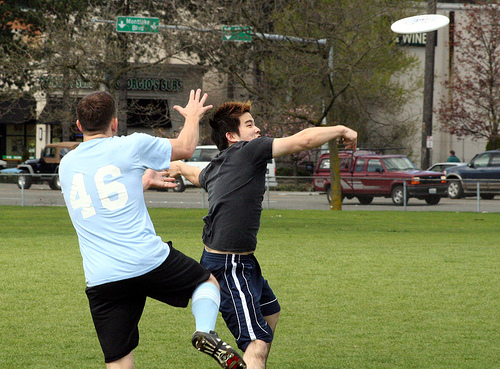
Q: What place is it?
A: It is a field.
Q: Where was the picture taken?
A: It was taken at the field.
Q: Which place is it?
A: It is a field.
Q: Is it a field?
A: Yes, it is a field.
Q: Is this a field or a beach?
A: It is a field.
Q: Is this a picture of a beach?
A: No, the picture is showing a field.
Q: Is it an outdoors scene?
A: Yes, it is outdoors.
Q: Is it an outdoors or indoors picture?
A: It is outdoors.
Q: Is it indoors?
A: No, it is outdoors.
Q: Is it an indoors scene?
A: No, it is outdoors.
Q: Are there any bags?
A: No, there are no bags.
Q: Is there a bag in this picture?
A: No, there are no bags.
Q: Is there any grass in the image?
A: Yes, there is grass.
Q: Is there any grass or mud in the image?
A: Yes, there is grass.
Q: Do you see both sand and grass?
A: No, there is grass but no sand.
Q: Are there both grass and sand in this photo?
A: No, there is grass but no sand.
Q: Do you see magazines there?
A: No, there are no magazines.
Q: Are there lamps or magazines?
A: No, there are no magazines or lamps.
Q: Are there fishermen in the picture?
A: No, there are no fishermen.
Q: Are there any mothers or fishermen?
A: No, there are no fishermen or mothers.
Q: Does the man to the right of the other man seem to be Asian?
A: Yes, the man is asian.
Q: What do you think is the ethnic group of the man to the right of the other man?
A: The man is asian.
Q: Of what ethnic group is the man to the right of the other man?
A: The man is asian.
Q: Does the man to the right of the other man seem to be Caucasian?
A: No, the man is asian.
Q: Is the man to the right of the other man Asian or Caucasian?
A: The man is asian.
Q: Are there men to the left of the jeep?
A: No, the man is to the right of the jeep.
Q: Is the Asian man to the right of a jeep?
A: Yes, the man is to the right of a jeep.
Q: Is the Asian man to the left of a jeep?
A: No, the man is to the right of a jeep.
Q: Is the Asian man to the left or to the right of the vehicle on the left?
A: The man is to the right of the jeep.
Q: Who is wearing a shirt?
A: The man is wearing a shirt.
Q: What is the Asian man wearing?
A: The man is wearing a shirt.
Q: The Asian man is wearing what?
A: The man is wearing a shirt.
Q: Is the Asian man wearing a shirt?
A: Yes, the man is wearing a shirt.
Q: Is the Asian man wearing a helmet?
A: No, the man is wearing a shirt.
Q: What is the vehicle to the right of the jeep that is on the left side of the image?
A: The vehicle is a van.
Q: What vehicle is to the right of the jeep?
A: The vehicle is a van.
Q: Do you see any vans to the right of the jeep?
A: Yes, there is a van to the right of the jeep.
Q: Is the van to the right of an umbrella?
A: No, the van is to the right of the jeep.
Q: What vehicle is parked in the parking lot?
A: The vehicle is a van.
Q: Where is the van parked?
A: The van is parked in the parking lot.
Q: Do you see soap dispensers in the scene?
A: No, there are no soap dispensers.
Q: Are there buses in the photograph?
A: No, there are no buses.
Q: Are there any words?
A: Yes, there are words.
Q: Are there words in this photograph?
A: Yes, there are words.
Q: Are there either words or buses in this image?
A: Yes, there are words.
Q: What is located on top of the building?
A: The words are on top of the building.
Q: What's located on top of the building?
A: The words are on top of the building.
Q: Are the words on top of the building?
A: Yes, the words are on top of the building.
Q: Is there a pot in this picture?
A: No, there are no pots.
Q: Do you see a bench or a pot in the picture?
A: No, there are no pots or benches.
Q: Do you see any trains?
A: No, there are no trains.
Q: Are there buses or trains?
A: No, there are no trains or buses.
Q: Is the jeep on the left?
A: Yes, the jeep is on the left of the image.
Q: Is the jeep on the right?
A: No, the jeep is on the left of the image.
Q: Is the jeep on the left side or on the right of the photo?
A: The jeep is on the left of the image.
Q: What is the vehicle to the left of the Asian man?
A: The vehicle is a jeep.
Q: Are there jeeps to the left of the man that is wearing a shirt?
A: Yes, there is a jeep to the left of the man.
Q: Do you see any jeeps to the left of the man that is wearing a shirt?
A: Yes, there is a jeep to the left of the man.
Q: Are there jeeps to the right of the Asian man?
A: No, the jeep is to the left of the man.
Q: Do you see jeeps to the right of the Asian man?
A: No, the jeep is to the left of the man.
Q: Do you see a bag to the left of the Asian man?
A: No, there is a jeep to the left of the man.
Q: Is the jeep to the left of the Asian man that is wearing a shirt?
A: Yes, the jeep is to the left of the man.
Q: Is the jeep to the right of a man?
A: No, the jeep is to the left of a man.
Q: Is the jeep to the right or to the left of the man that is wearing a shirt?
A: The jeep is to the left of the man.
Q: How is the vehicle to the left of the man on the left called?
A: The vehicle is a jeep.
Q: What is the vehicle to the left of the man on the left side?
A: The vehicle is a jeep.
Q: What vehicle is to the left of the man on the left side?
A: The vehicle is a jeep.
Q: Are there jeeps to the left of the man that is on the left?
A: Yes, there is a jeep to the left of the man.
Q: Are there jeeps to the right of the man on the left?
A: No, the jeep is to the left of the man.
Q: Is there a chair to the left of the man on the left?
A: No, there is a jeep to the left of the man.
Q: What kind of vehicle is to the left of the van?
A: The vehicle is a jeep.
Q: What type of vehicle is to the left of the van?
A: The vehicle is a jeep.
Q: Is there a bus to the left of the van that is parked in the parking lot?
A: No, there is a jeep to the left of the van.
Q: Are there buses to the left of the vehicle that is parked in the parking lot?
A: No, there is a jeep to the left of the van.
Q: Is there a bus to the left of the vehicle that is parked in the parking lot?
A: No, there is a jeep to the left of the van.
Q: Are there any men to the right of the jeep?
A: Yes, there are men to the right of the jeep.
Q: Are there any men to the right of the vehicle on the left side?
A: Yes, there are men to the right of the jeep.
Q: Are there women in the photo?
A: No, there are no women.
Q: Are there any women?
A: No, there are no women.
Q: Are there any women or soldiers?
A: No, there are no women or soldiers.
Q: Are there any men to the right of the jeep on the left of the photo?
A: Yes, there is a man to the right of the jeep.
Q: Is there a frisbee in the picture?
A: Yes, there is a frisbee.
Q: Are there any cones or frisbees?
A: Yes, there is a frisbee.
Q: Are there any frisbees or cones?
A: Yes, there is a frisbee.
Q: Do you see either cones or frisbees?
A: Yes, there is a frisbee.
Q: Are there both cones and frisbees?
A: No, there is a frisbee but no cones.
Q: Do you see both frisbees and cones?
A: No, there is a frisbee but no cones.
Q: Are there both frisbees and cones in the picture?
A: No, there is a frisbee but no cones.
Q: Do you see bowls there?
A: No, there are no bowls.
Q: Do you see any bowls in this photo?
A: No, there are no bowls.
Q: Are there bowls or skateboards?
A: No, there are no bowls or skateboards.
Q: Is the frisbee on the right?
A: Yes, the frisbee is on the right of the image.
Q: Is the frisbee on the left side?
A: No, the frisbee is on the right of the image.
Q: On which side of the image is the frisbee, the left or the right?
A: The frisbee is on the right of the image.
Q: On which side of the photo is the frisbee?
A: The frisbee is on the right of the image.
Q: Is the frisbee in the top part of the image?
A: Yes, the frisbee is in the top of the image.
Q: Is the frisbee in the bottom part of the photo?
A: No, the frisbee is in the top of the image.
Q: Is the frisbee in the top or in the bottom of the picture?
A: The frisbee is in the top of the image.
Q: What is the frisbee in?
A: The frisbee is in the air.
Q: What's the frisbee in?
A: The frisbee is in the air.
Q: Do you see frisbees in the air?
A: Yes, there is a frisbee in the air.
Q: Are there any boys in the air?
A: No, there is a frisbee in the air.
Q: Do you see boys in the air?
A: No, there is a frisbee in the air.